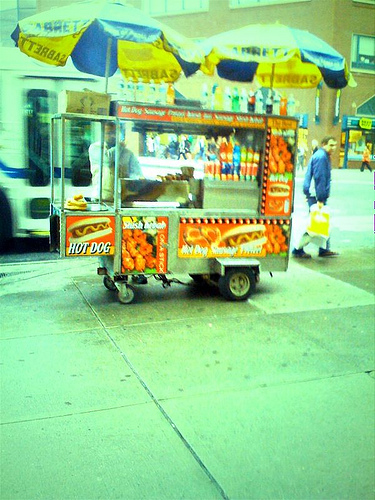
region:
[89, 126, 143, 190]
a man serving hot dogs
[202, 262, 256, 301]
one small black tire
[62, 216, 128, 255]
a red and yellow hot dog sign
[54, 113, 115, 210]
a glass incased display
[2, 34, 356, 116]
two sabrett blue and yellow umbrellas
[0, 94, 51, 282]
a commuter bus in motion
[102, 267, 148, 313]
two small black wheels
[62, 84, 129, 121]
large cardboard box on cart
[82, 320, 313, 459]
gray wet sidewalk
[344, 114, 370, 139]
best buy yellow and black sign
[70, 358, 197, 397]
small black spots on the ground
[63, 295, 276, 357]
lines on the sidewalk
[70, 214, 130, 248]
picture on side of food cart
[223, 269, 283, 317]
large black wheels on cart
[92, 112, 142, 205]
man standing behind the food cart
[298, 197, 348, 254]
large yellow bag in man's hand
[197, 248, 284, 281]
long silver cover on wheel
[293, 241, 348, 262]
black sneakers on man's feet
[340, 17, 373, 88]
large window in building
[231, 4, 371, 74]
large brown building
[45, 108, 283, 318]
food cart on street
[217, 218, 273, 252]
picture of hot dog on cart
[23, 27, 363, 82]
two umbrellas on cart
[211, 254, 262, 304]
wheel with cover underneath cart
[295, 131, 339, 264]
man walking with bag in hand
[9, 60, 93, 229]
moving bus on street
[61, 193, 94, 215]
food in glass case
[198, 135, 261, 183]
beverage bottles on display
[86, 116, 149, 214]
man standing next to cart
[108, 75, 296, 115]
beverage bottles on top of cart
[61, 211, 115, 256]
hot dog advertisement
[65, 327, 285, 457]
gum stained side walk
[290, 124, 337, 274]
man walking down a street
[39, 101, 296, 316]
hot dog cart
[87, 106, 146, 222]
hot dog vendor man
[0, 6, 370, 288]
city street behind a hot dog cart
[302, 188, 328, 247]
hand holding a yellow and white bag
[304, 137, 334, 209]
blue and white jacket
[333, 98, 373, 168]
store sign on a store front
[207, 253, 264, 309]
wheel on a hot dog cart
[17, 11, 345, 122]
two umbrella on a hotdog stand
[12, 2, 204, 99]
umbrella is yellow and blue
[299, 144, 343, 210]
man is wearing a jacket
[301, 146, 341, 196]
the jacket is blue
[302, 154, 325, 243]
man carrying a bag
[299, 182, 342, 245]
the bag is yellow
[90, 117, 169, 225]
a man behind the kiosk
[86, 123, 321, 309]
the kiosk is a hotdog stand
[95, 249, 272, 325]
the kiosk has wheels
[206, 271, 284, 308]
the wheels are black